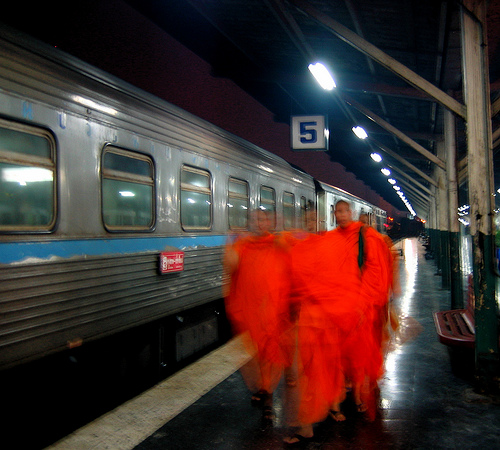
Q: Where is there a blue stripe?
A: Running down the side of the train.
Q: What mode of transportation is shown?
A: Train.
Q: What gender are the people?
A: Male.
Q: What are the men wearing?
A: Orange robes.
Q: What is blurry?
A: The men.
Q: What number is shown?
A: 5.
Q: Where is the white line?
A: Between the men and the train.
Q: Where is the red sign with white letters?
A: Side of train.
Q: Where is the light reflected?
A: Floor.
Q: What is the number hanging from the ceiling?
A: 5.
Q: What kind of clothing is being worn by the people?
A: Robes.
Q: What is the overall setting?
A: Train station.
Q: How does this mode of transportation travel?
A: On tracks.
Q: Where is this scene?
A: A train platform.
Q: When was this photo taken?
A: At night.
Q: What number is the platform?
A: 5.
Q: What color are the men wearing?
A: Orange.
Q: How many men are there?
A: Three.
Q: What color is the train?
A: Silver.